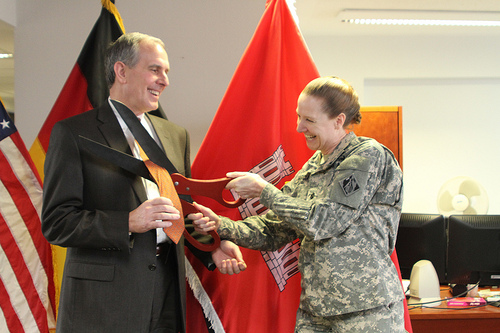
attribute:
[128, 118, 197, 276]
tie — mans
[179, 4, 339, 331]
flag — red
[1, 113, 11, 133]
star —  on the flag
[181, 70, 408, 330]
woman — red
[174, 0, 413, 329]
flag — large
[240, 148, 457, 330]
uniform — military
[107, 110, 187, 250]
orange tie — smiling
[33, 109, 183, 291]
jacket — black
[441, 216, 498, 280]
monitor — black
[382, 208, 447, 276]
monitor — black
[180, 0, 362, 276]
flag — red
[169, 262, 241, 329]
fringe — white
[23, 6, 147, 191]
flag — black, red, yellow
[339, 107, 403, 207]
door — closed, light brown, wood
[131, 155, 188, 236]
necktie — orange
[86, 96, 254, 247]
scissors — oversized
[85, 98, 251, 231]
scissors — red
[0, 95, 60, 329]
flag — american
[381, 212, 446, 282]
computer monitor — black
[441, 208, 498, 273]
computer monitor — black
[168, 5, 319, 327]
flag — red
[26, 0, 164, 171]
flag — red, yellow, black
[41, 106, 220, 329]
suit coat — gray